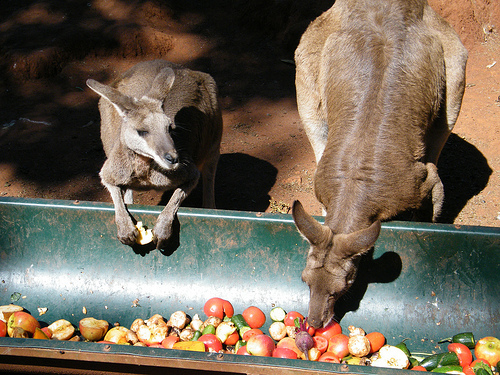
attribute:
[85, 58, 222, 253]
kangaroo — looking, brown, a baby, feeding, smaller, small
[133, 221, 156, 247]
fruit — mixed, bunch, cut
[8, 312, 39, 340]
fruit — red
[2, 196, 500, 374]
tub — green, big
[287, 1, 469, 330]
kangaroo — big, larger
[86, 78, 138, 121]
ears — long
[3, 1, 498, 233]
dirt — brown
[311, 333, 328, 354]
tomato — red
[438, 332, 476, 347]
zucchini — halved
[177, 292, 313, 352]
veggies — bunch